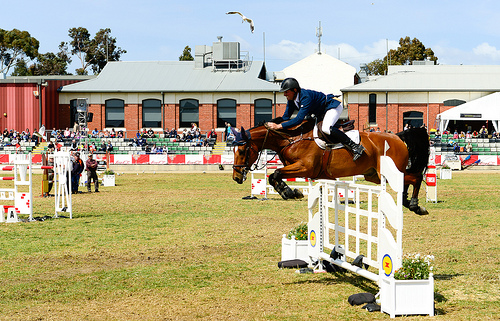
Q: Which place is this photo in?
A: It is at the field.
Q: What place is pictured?
A: It is a field.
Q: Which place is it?
A: It is a field.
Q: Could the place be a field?
A: Yes, it is a field.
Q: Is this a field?
A: Yes, it is a field.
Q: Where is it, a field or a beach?
A: It is a field.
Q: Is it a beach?
A: No, it is a field.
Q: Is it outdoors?
A: Yes, it is outdoors.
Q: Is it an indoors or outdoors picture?
A: It is outdoors.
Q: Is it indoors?
A: No, it is outdoors.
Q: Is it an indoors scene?
A: No, it is outdoors.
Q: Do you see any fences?
A: Yes, there is a fence.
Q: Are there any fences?
A: Yes, there is a fence.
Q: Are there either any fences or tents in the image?
A: Yes, there is a fence.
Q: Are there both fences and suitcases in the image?
A: No, there is a fence but no suitcases.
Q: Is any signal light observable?
A: No, there are no traffic lights.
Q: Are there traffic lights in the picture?
A: No, there are no traffic lights.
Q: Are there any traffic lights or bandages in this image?
A: No, there are no traffic lights or bandages.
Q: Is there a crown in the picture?
A: No, there are no crowns.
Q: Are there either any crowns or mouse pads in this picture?
A: No, there are no crowns or mouse pads.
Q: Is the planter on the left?
A: No, the planter is on the right of the image.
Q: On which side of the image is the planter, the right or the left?
A: The planter is on the right of the image.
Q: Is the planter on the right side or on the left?
A: The planter is on the right of the image.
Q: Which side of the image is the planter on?
A: The planter is on the right of the image.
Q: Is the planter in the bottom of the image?
A: Yes, the planter is in the bottom of the image.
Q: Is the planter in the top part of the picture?
A: No, the planter is in the bottom of the image.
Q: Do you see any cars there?
A: No, there are no cars.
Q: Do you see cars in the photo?
A: No, there are no cars.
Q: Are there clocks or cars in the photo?
A: No, there are no cars or clocks.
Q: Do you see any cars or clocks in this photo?
A: No, there are no cars or clocks.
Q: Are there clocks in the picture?
A: No, there are no clocks.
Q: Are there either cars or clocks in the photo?
A: No, there are no clocks or cars.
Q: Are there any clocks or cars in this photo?
A: No, there are no clocks or cars.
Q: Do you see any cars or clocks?
A: No, there are no clocks or cars.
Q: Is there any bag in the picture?
A: No, there are no bags.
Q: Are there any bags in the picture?
A: No, there are no bags.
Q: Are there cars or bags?
A: No, there are no bags or cars.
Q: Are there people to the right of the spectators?
A: Yes, there is a person to the right of the spectators.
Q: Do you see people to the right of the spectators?
A: Yes, there is a person to the right of the spectators.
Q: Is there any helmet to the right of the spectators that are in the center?
A: No, there is a person to the right of the spectators.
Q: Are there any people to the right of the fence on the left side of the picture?
A: Yes, there is a person to the right of the fence.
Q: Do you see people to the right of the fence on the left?
A: Yes, there is a person to the right of the fence.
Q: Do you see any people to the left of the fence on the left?
A: No, the person is to the right of the fence.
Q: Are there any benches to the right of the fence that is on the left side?
A: No, there is a person to the right of the fence.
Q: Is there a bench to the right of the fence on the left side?
A: No, there is a person to the right of the fence.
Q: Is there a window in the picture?
A: Yes, there is a window.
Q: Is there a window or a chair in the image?
A: Yes, there is a window.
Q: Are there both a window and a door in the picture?
A: No, there is a window but no doors.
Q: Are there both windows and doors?
A: No, there is a window but no doors.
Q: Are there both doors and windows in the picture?
A: No, there is a window but no doors.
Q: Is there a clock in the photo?
A: No, there are no clocks.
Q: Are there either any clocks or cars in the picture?
A: No, there are no clocks or cars.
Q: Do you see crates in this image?
A: No, there are no crates.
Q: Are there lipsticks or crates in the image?
A: No, there are no crates or lipsticks.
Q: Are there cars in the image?
A: No, there are no cars.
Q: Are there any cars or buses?
A: No, there are no cars or buses.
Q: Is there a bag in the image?
A: No, there are no bags.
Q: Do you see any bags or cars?
A: No, there are no bags or cars.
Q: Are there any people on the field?
A: Yes, there is a person on the field.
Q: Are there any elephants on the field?
A: No, there is a person on the field.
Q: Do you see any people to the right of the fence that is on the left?
A: Yes, there is a person to the right of the fence.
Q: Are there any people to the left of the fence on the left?
A: No, the person is to the right of the fence.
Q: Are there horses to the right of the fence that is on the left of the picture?
A: No, there is a person to the right of the fence.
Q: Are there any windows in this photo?
A: Yes, there is a window.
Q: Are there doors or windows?
A: Yes, there is a window.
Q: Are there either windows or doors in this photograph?
A: Yes, there is a window.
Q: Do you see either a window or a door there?
A: Yes, there is a window.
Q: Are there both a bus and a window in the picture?
A: No, there is a window but no buses.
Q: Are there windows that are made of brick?
A: Yes, there is a window that is made of brick.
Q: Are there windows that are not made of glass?
A: Yes, there is a window that is made of brick.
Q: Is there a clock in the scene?
A: No, there are no clocks.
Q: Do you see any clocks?
A: No, there are no clocks.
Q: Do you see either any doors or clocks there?
A: No, there are no clocks or doors.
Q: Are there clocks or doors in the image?
A: No, there are no clocks or doors.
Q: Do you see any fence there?
A: Yes, there is a fence.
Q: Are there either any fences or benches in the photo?
A: Yes, there is a fence.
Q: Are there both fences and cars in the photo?
A: No, there is a fence but no cars.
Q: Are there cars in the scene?
A: No, there are no cars.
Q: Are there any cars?
A: No, there are no cars.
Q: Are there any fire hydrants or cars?
A: No, there are no cars or fire hydrants.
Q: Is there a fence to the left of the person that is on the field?
A: Yes, there is a fence to the left of the person.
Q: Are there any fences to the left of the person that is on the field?
A: Yes, there is a fence to the left of the person.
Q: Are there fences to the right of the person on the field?
A: No, the fence is to the left of the person.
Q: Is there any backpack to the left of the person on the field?
A: No, there is a fence to the left of the person.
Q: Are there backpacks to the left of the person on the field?
A: No, there is a fence to the left of the person.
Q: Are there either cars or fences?
A: Yes, there is a fence.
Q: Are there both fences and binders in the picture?
A: No, there is a fence but no binders.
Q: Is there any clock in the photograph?
A: No, there are no clocks.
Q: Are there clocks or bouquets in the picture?
A: No, there are no clocks or bouquets.